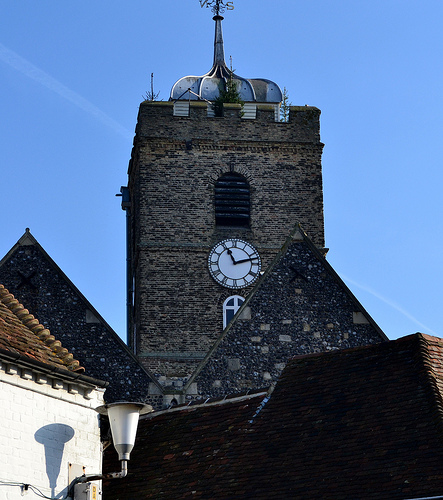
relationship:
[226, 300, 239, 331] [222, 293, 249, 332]
window with trim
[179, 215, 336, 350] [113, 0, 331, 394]
clock on building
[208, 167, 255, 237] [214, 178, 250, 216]
window with slats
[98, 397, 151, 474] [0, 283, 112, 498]
light beside building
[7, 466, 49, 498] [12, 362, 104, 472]
lamp wire side building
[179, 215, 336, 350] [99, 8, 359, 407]
clock on building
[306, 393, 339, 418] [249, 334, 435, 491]
brick on roof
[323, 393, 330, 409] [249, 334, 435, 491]
brick on roof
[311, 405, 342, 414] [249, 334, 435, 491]
brick on roof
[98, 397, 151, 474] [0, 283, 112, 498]
light on building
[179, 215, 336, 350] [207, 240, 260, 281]
clock shows time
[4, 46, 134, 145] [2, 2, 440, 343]
white line in sky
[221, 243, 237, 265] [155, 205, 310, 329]
hand on clock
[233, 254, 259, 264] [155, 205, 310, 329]
hand on clock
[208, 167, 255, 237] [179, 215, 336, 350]
window above clock